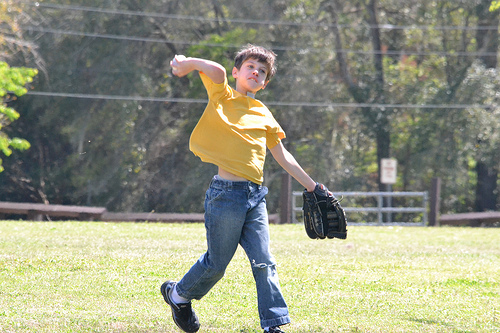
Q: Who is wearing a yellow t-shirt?
A: A child.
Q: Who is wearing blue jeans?
A: A boy.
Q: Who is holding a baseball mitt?
A: A boy.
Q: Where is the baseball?
A: In the boy's hand.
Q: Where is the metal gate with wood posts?
A: Behind the boy.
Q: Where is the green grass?
A: In the field.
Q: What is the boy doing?
A: Throwing a ball.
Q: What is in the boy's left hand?
A: Glove.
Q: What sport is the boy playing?
A: Baseball.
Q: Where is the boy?
A: Field.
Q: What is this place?
A: Park.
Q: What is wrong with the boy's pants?
A: Ripped.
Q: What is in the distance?
A: Sign.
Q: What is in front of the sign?
A: Fence.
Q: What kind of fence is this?
A: Metal.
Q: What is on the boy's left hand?
A: Baseball glove.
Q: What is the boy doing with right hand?
A: Throwing the ball.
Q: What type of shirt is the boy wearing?
A: T shirt.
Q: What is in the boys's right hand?
A: Baseball.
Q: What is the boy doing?
A: Throwing a baseball.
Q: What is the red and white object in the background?
A: Sign.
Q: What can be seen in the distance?
A: Trees.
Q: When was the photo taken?
A: Daytime.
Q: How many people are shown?
A: One.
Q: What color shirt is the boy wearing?
A: Yellow.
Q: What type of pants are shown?
A: Jeans.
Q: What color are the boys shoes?
A: Black.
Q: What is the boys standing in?
A: Grass.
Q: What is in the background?
A: Trees.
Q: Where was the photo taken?
A: In a park.